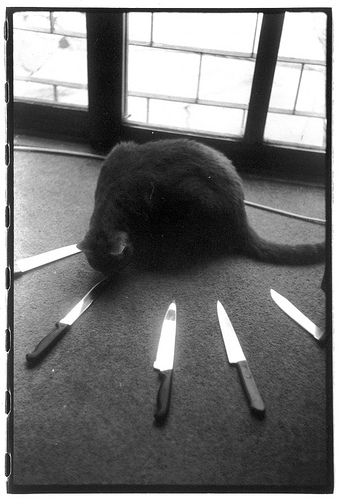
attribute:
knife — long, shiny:
[27, 275, 117, 363]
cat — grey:
[76, 139, 326, 277]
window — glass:
[12, 10, 327, 191]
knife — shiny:
[153, 298, 178, 423]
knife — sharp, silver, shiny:
[270, 287, 326, 345]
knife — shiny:
[11, 241, 81, 275]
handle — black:
[26, 322, 73, 362]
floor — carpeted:
[14, 131, 327, 485]